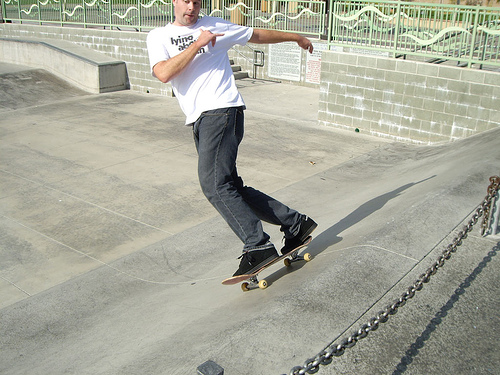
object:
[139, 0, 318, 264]
man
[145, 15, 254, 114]
shirt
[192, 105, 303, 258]
pants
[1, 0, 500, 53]
rail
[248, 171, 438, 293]
shadow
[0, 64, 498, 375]
ground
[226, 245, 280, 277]
shoe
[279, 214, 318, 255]
shoe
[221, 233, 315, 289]
skateboard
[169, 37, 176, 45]
letters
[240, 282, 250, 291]
wheel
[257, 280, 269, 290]
wheel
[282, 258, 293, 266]
wheel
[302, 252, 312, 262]
wheel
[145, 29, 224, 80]
arm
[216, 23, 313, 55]
arm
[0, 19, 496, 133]
wall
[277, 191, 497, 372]
chain